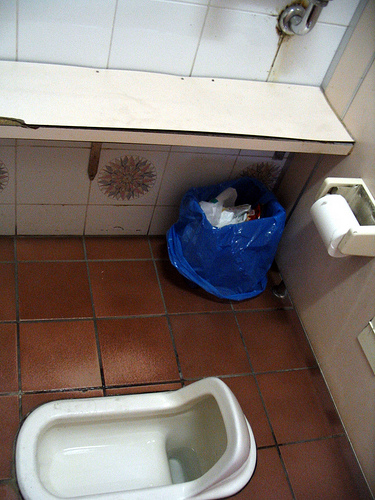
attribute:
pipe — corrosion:
[273, 0, 331, 35]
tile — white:
[19, 4, 352, 83]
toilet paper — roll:
[309, 190, 360, 254]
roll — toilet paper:
[310, 192, 360, 256]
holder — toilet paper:
[314, 176, 373, 256]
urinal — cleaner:
[12, 363, 271, 498]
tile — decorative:
[100, 158, 156, 209]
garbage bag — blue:
[160, 185, 282, 306]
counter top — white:
[17, 43, 326, 154]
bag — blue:
[166, 176, 287, 299]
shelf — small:
[165, 71, 313, 160]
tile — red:
[87, 257, 166, 314]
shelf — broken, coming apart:
[1, 57, 33, 139]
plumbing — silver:
[270, 1, 324, 37]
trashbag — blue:
[163, 167, 285, 302]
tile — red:
[94, 311, 184, 389]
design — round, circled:
[95, 153, 158, 202]